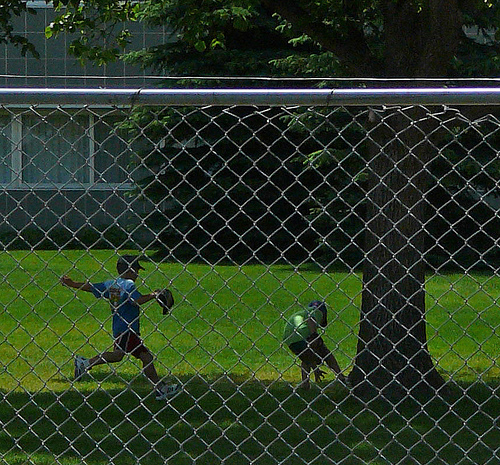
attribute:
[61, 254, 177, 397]
boy — playing, running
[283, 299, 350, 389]
boy — bending, playing, little, reaching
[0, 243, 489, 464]
yard — green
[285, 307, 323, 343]
shirt — green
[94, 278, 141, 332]
shirt — blue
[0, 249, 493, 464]
grass — green, manicured, lush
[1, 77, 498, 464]
fence — chain link, large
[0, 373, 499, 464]
shadow — large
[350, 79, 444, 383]
trunk — large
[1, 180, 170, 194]
frame — white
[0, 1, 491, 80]
leaves — green, flowering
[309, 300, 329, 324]
hat — blue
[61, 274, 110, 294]
arm — extended